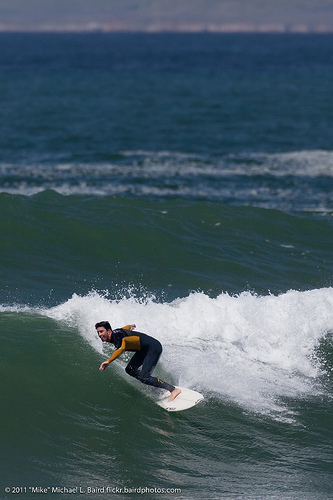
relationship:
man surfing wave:
[93, 323, 179, 401] [18, 308, 331, 412]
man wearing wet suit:
[93, 323, 179, 401] [112, 331, 173, 390]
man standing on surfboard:
[93, 323, 179, 401] [147, 378, 203, 413]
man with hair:
[93, 323, 179, 401] [93, 321, 112, 329]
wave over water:
[18, 308, 331, 412] [1, 32, 332, 499]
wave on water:
[18, 308, 331, 412] [1, 32, 332, 499]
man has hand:
[93, 323, 179, 401] [98, 361, 109, 373]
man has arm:
[93, 323, 179, 401] [104, 338, 127, 367]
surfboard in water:
[147, 378, 203, 413] [1, 32, 332, 499]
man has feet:
[93, 323, 179, 401] [162, 388, 180, 402]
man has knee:
[93, 323, 179, 401] [133, 368, 158, 378]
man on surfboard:
[93, 323, 179, 401] [147, 378, 203, 413]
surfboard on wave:
[147, 378, 203, 413] [18, 308, 331, 412]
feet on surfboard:
[162, 388, 180, 402] [147, 378, 203, 413]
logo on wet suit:
[154, 374, 165, 385] [112, 331, 173, 390]